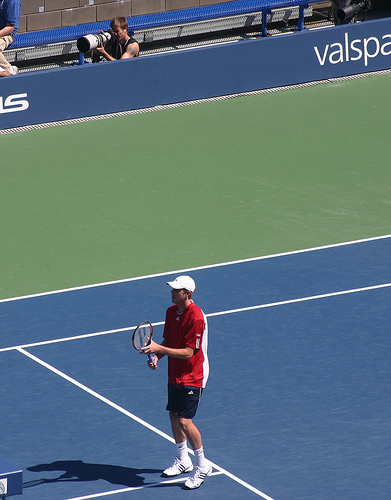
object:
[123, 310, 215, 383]
arm person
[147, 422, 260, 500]
feet person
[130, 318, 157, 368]
racket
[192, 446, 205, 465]
sock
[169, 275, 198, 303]
head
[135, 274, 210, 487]
person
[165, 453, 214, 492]
feet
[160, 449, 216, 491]
shoes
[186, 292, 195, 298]
ear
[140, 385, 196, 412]
shorts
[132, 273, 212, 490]
man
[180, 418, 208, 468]
leg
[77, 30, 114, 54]
camera lens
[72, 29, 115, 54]
camera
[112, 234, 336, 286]
lines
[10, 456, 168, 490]
shadow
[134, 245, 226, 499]
tennis player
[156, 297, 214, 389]
shirt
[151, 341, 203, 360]
arm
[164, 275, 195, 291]
cap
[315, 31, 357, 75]
letters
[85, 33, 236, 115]
wall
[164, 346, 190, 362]
tattoo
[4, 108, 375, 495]
court